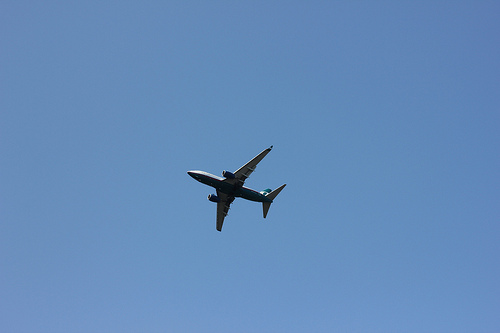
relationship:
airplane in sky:
[183, 139, 289, 235] [2, 2, 500, 332]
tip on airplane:
[185, 170, 201, 178] [183, 139, 289, 235]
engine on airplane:
[220, 172, 238, 179] [183, 139, 289, 235]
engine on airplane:
[207, 193, 218, 202] [183, 139, 289, 235]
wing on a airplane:
[221, 141, 274, 184] [183, 139, 289, 235]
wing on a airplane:
[213, 188, 236, 231] [183, 139, 289, 235]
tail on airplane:
[257, 184, 288, 216] [183, 139, 289, 235]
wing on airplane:
[221, 141, 274, 184] [183, 139, 289, 235]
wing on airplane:
[213, 188, 236, 231] [183, 139, 289, 235]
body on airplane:
[196, 172, 269, 203] [183, 139, 289, 235]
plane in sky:
[183, 139, 289, 235] [2, 2, 500, 332]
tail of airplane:
[257, 184, 288, 216] [183, 139, 289, 235]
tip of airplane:
[185, 170, 201, 178] [183, 139, 289, 235]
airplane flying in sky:
[183, 139, 289, 235] [2, 2, 500, 332]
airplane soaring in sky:
[183, 139, 289, 235] [2, 2, 500, 332]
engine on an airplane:
[220, 172, 238, 179] [183, 139, 289, 235]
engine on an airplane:
[207, 193, 218, 202] [183, 139, 289, 235]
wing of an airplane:
[221, 141, 274, 184] [183, 139, 289, 235]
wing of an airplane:
[213, 188, 236, 231] [183, 139, 289, 235]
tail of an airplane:
[257, 184, 288, 216] [183, 139, 289, 235]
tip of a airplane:
[185, 170, 201, 178] [183, 139, 289, 235]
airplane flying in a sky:
[183, 139, 289, 235] [2, 2, 500, 332]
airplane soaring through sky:
[183, 139, 289, 235] [2, 2, 500, 332]